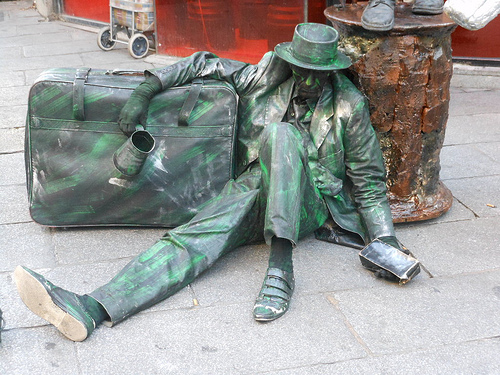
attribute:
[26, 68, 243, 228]
suitcase — green, gray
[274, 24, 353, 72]
hat — green, gray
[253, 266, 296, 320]
shoe — green, gray, painted, worn out, worn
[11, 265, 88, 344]
sole — white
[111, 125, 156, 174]
mug — green, gray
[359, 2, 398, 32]
shoe — dirty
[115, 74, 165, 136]
glove — green, gray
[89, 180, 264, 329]
pant leg — green, gray, painted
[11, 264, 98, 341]
shoe — painted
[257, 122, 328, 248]
pant leg — painted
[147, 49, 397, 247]
jacket — painted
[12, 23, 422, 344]
person — painted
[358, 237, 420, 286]
item — painted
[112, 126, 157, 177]
can — painted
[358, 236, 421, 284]
box — small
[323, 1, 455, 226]
pedestal — shaped like a stump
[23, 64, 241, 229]
travel bag — large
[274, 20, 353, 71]
fedora hat — green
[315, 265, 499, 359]
tile — cement